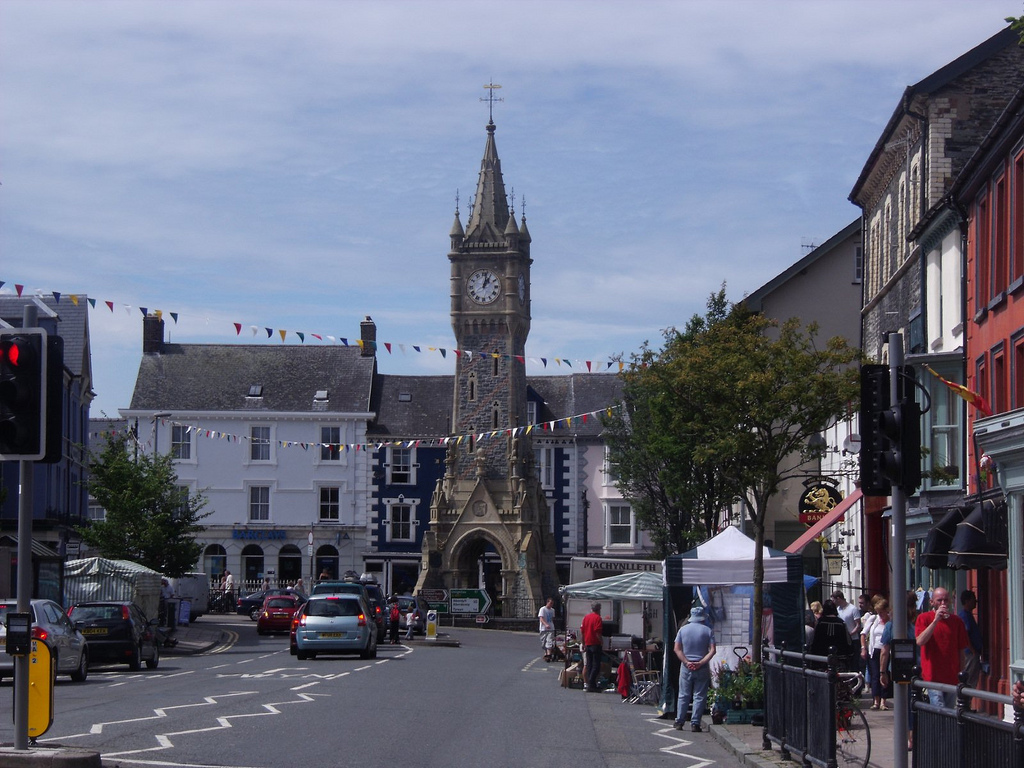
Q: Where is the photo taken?
A: Main street.